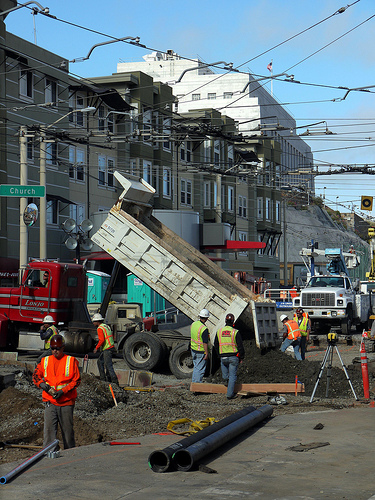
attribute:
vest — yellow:
[195, 305, 209, 319]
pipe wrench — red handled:
[102, 437, 142, 447]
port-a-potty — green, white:
[80, 270, 109, 315]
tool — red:
[107, 440, 141, 444]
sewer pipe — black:
[146, 402, 208, 485]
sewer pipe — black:
[188, 412, 271, 457]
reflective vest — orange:
[36, 351, 83, 399]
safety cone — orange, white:
[347, 337, 370, 373]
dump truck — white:
[99, 186, 272, 349]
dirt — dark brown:
[223, 340, 325, 391]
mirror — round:
[19, 198, 43, 233]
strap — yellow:
[160, 416, 211, 439]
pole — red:
[350, 339, 373, 400]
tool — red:
[105, 435, 141, 447]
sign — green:
[0, 178, 55, 205]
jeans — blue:
[205, 349, 243, 397]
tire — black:
[123, 328, 163, 377]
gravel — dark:
[217, 332, 347, 381]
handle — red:
[107, 435, 147, 451]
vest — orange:
[33, 357, 82, 395]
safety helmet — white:
[196, 306, 212, 321]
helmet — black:
[42, 331, 71, 357]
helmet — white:
[196, 310, 210, 320]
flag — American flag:
[262, 52, 290, 92]